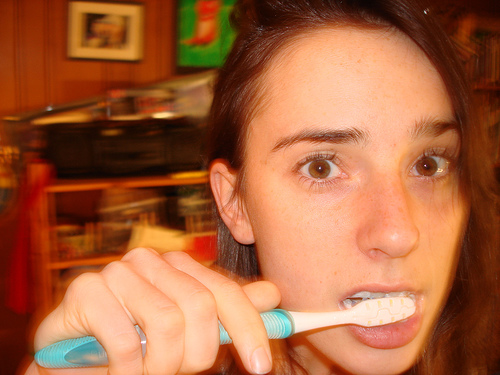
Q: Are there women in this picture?
A: Yes, there is a woman.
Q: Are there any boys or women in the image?
A: Yes, there is a woman.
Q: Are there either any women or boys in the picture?
A: Yes, there is a woman.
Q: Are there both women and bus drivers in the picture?
A: No, there is a woman but no bus drivers.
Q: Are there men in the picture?
A: No, there are no men.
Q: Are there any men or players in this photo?
A: No, there are no men or players.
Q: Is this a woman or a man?
A: This is a woman.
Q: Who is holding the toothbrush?
A: The woman is holding the toothbrush.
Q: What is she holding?
A: The woman is holding the toothbrush.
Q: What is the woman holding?
A: The woman is holding the toothbrush.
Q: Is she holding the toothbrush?
A: Yes, the woman is holding the toothbrush.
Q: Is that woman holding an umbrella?
A: No, the woman is holding the toothbrush.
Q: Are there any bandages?
A: No, there are no bandages.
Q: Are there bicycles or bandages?
A: No, there are no bandages or bicycles.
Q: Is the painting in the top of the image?
A: Yes, the painting is in the top of the image.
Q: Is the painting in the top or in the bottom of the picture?
A: The painting is in the top of the image.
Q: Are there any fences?
A: No, there are no fences.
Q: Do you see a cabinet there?
A: Yes, there is a cabinet.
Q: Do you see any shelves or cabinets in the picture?
A: Yes, there is a cabinet.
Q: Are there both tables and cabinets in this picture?
A: No, there is a cabinet but no tables.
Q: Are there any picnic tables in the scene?
A: No, there are no picnic tables.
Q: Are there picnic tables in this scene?
A: No, there are no picnic tables.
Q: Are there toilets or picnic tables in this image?
A: No, there are no picnic tables or toilets.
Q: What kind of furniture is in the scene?
A: The furniture is a cabinet.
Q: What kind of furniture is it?
A: The piece of furniture is a cabinet.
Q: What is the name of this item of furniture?
A: This is a cabinet.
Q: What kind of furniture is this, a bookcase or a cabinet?
A: This is a cabinet.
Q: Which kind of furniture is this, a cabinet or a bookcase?
A: This is a cabinet.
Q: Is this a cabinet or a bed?
A: This is a cabinet.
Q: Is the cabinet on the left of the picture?
A: Yes, the cabinet is on the left of the image.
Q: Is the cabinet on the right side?
A: No, the cabinet is on the left of the image.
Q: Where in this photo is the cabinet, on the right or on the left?
A: The cabinet is on the left of the image.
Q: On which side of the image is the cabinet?
A: The cabinet is on the left of the image.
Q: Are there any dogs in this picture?
A: No, there are no dogs.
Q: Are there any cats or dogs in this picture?
A: No, there are no dogs or cats.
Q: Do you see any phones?
A: No, there are no phones.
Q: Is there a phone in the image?
A: No, there are no phones.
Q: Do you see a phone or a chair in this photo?
A: No, there are no phones or chairs.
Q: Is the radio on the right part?
A: No, the radio is on the left of the image.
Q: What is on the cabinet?
A: The radio is on the cabinet.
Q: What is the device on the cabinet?
A: The device is a radio.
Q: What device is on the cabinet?
A: The device is a radio.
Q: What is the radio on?
A: The radio is on the cabinet.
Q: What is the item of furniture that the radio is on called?
A: The piece of furniture is a cabinet.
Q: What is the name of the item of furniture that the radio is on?
A: The piece of furniture is a cabinet.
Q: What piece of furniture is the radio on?
A: The radio is on the cabinet.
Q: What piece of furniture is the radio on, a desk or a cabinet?
A: The radio is on a cabinet.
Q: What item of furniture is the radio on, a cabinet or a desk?
A: The radio is on a cabinet.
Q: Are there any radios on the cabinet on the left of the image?
A: Yes, there is a radio on the cabinet.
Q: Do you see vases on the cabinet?
A: No, there is a radio on the cabinet.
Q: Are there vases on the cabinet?
A: No, there is a radio on the cabinet.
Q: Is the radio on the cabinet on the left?
A: Yes, the radio is on the cabinet.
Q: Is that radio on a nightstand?
A: No, the radio is on the cabinet.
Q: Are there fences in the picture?
A: No, there are no fences.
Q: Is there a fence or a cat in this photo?
A: No, there are no fences or cats.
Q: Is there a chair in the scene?
A: No, there are no chairs.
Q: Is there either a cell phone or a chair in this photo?
A: No, there are no chairs or cell phones.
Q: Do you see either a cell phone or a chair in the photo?
A: No, there are no chairs or cell phones.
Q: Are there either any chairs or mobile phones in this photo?
A: No, there are no chairs or mobile phones.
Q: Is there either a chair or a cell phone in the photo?
A: No, there are no chairs or cell phones.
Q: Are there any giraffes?
A: No, there are no giraffes.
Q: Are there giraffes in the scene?
A: No, there are no giraffes.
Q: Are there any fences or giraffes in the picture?
A: No, there are no giraffes or fences.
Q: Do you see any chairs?
A: No, there are no chairs.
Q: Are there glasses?
A: No, there are no glasses.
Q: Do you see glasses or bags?
A: No, there are no glasses or bags.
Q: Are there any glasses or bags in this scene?
A: No, there are no glasses or bags.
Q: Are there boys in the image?
A: No, there are no boys.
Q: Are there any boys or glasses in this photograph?
A: No, there are no boys or glasses.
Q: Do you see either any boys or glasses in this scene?
A: No, there are no boys or glasses.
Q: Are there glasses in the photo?
A: No, there are no glasses.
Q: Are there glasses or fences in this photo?
A: No, there are no glasses or fences.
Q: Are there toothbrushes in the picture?
A: Yes, there is a toothbrush.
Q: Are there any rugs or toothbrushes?
A: Yes, there is a toothbrush.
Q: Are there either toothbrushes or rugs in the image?
A: Yes, there is a toothbrush.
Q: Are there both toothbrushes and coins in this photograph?
A: No, there is a toothbrush but no coins.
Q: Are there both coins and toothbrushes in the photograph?
A: No, there is a toothbrush but no coins.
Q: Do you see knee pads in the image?
A: No, there are no knee pads.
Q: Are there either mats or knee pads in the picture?
A: No, there are no knee pads or mats.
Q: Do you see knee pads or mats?
A: No, there are no knee pads or mats.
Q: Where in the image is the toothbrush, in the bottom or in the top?
A: The toothbrush is in the bottom of the image.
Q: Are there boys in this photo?
A: No, there are no boys.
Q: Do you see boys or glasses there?
A: No, there are no boys or glasses.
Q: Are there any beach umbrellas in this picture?
A: No, there are no beach umbrellas.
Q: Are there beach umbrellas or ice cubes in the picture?
A: No, there are no beach umbrellas or ice cubes.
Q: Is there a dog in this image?
A: No, there are no dogs.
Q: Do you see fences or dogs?
A: No, there are no dogs or fences.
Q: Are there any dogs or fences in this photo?
A: No, there are no dogs or fences.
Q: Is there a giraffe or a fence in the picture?
A: No, there are no fences or giraffes.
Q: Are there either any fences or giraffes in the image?
A: No, there are no fences or giraffes.